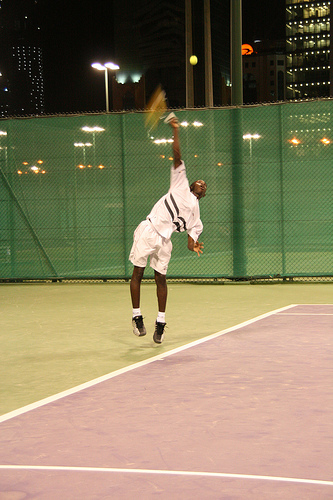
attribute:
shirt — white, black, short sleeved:
[144, 157, 204, 245]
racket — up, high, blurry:
[139, 97, 164, 138]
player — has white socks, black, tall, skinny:
[96, 104, 243, 363]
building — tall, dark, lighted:
[18, 25, 43, 106]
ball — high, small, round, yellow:
[187, 51, 197, 66]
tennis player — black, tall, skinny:
[115, 118, 225, 345]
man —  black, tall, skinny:
[100, 118, 240, 337]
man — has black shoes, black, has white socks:
[125, 117, 201, 344]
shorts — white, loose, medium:
[126, 216, 173, 277]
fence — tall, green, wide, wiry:
[0, 95, 332, 284]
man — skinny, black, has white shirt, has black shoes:
[61, 108, 219, 355]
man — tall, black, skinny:
[66, 98, 235, 347]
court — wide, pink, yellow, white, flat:
[0, 281, 332, 497]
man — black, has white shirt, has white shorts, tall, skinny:
[128, 118, 206, 343]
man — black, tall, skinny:
[96, 78, 219, 345]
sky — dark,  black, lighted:
[2, 2, 331, 119]